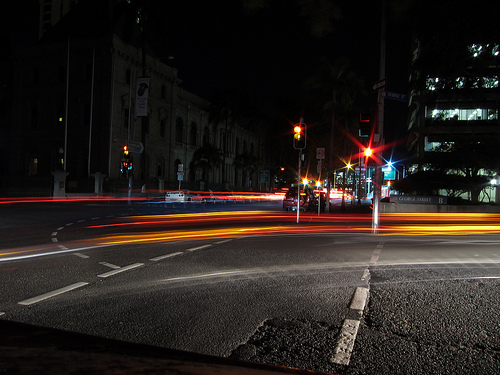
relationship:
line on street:
[0, 235, 239, 313] [2, 200, 496, 372]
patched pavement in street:
[228, 264, 499, 374] [2, 200, 496, 372]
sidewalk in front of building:
[315, 196, 498, 231] [426, 27, 497, 119]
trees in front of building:
[178, 142, 270, 183] [65, 35, 301, 196]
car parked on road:
[282, 179, 315, 208] [3, 188, 495, 373]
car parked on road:
[161, 187, 187, 203] [3, 188, 495, 373]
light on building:
[446, 106, 460, 121] [373, 34, 498, 228]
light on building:
[426, 106, 448, 121] [373, 34, 498, 228]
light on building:
[464, 107, 479, 122] [373, 34, 498, 228]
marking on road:
[96, 258, 146, 280] [1, 211, 498, 373]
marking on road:
[148, 248, 185, 261] [1, 211, 498, 373]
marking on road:
[17, 277, 90, 305] [1, 211, 498, 373]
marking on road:
[56, 242, 89, 259] [1, 211, 498, 373]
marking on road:
[184, 240, 211, 253] [1, 211, 498, 373]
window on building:
[426, 101, 495, 124] [366, 8, 496, 204]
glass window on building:
[430, 106, 442, 119] [418, 85, 485, 159]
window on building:
[444, 106, 462, 121] [375, 13, 493, 214]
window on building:
[481, 107, 498, 118] [405, 31, 492, 192]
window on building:
[419, 136, 444, 151] [373, 34, 498, 228]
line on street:
[322, 215, 398, 373] [2, 200, 496, 372]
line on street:
[6, 195, 178, 262] [2, 200, 496, 372]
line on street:
[15, 220, 258, 341] [2, 200, 496, 372]